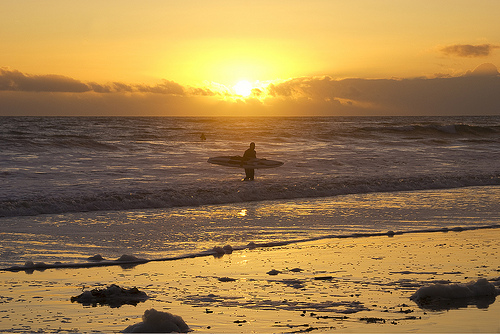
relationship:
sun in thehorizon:
[167, 52, 284, 97] [6, 4, 496, 117]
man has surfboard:
[244, 142, 256, 181] [206, 154, 283, 168]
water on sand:
[310, 128, 422, 173] [55, 209, 491, 330]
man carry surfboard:
[244, 142, 256, 181] [204, 136, 286, 183]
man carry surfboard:
[244, 142, 256, 181] [205, 152, 284, 172]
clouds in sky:
[314, 63, 499, 113] [24, 16, 484, 104]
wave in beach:
[332, 168, 387, 195] [306, 190, 448, 278]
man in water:
[241, 138, 261, 190] [0, 116, 497, 271]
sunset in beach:
[148, 60, 374, 122] [76, 118, 461, 298]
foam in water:
[11, 223, 467, 272] [0, 116, 497, 271]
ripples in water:
[0, 162, 497, 216] [0, 115, 497, 332]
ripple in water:
[96, 169, 183, 181] [0, 116, 497, 271]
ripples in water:
[299, 120, 490, 242] [72, 120, 243, 228]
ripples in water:
[262, 122, 338, 146] [66, 97, 396, 200]